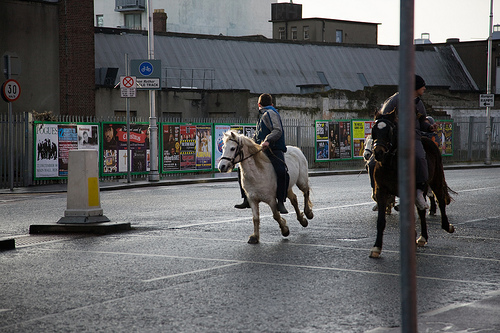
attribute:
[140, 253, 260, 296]
line — white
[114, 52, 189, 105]
sign — street